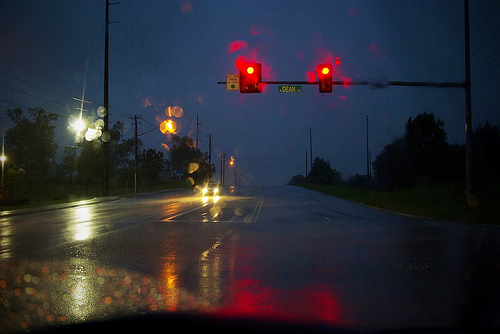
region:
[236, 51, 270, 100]
Red traffic light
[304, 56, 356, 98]
Red traffic light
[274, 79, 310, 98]
Street sign on traffic light pole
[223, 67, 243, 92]
Street sign on traffic light pole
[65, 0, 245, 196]
Power lines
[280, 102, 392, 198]
Power lines in the distance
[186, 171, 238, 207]
Oncoming car with it's headlights on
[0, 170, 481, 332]
Wet pavement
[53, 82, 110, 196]
Light from a lamp post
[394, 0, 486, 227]
Post for traffic lights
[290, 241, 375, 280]
part of a wet road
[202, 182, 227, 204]
part of some light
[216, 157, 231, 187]
part of some posts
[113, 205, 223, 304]
part of a window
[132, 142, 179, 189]
part of some trees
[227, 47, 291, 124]
part of a traffic light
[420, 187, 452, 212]
part of some grass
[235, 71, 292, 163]
part of the sky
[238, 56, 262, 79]
a red light in the street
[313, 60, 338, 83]
a red light in the street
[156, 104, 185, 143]
an orange light in the street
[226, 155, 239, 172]
an orange light in the street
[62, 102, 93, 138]
a white light in the street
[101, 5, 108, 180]
an electric pole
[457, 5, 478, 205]
an electric pole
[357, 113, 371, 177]
an electric pole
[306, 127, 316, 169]
an electric pole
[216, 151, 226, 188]
an electric pole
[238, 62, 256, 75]
a red traffic light on the pole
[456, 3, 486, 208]
a pole on the side of the road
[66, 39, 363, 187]
beads of water on the windshield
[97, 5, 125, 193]
a power pole on the side of the road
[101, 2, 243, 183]
power lines on the side of the road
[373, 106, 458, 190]
a tree on the side of the road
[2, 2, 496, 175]
the dark cloudy sky at night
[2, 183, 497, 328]
the wet road that the car is on.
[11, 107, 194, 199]
a line of trees on the side of the road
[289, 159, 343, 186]
the tree on the side of the road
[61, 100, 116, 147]
A streetlight shining in the rain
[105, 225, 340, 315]
Lights reflecting on a roadway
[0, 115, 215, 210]
Trees running alongside a road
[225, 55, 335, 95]
Two red lights stopping traffic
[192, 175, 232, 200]
An oncoming car hidden in reflecting lights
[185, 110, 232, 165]
Utility poles lining a road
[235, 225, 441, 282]
A wet roadway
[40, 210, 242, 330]
The path of a windshield wiper on a car's windshield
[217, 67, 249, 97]
A yield sign for left turn lanes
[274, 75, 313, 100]
A green road sign for Dean Rd